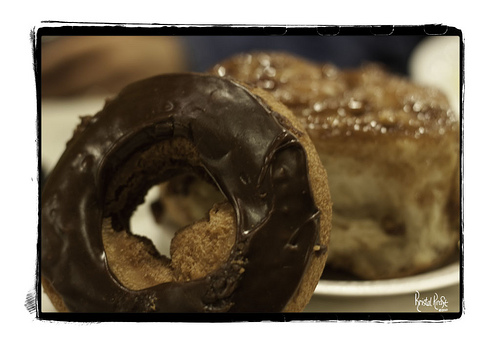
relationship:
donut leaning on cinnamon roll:
[39, 67, 330, 316] [213, 51, 453, 293]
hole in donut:
[135, 180, 200, 243] [106, 103, 216, 145]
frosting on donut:
[42, 70, 308, 321] [112, 91, 393, 331]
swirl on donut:
[250, 130, 305, 207] [39, 67, 330, 316]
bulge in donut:
[168, 200, 237, 284] [39, 67, 330, 316]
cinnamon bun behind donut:
[151, 47, 462, 274] [39, 67, 330, 316]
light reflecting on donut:
[65, 125, 125, 182] [47, 83, 292, 327]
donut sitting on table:
[39, 67, 330, 316] [44, 76, 148, 203]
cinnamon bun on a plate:
[151, 47, 462, 274] [118, 148, 460, 303]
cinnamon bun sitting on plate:
[151, 47, 462, 274] [137, 197, 462, 304]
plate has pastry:
[311, 250, 460, 300] [149, 49, 459, 280]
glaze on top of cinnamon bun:
[213, 48, 460, 138] [151, 47, 462, 274]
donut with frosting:
[39, 67, 330, 316] [42, 70, 308, 321]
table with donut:
[45, 93, 459, 309] [39, 67, 330, 316]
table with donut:
[45, 93, 459, 309] [207, 46, 460, 280]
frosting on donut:
[42, 70, 308, 321] [39, 67, 330, 316]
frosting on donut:
[42, 70, 308, 321] [25, 55, 349, 322]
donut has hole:
[39, 67, 330, 316] [118, 152, 215, 276]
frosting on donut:
[42, 70, 308, 321] [231, 160, 308, 266]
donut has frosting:
[39, 67, 330, 316] [42, 70, 308, 321]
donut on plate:
[39, 67, 330, 316] [71, 45, 452, 320]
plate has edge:
[311, 250, 460, 300] [331, 271, 453, 300]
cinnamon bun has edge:
[151, 47, 462, 274] [331, 115, 466, 273]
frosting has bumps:
[42, 70, 308, 321] [217, 111, 311, 306]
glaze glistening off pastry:
[213, 48, 460, 138] [149, 49, 459, 280]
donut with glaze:
[39, 67, 330, 316] [218, 58, 458, 157]